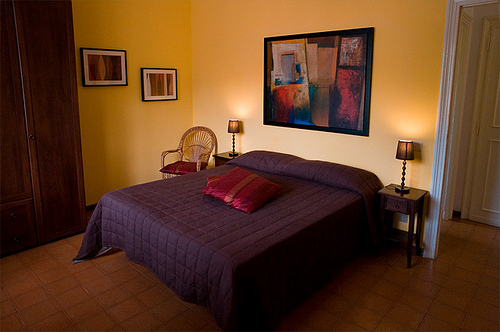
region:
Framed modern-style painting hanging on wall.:
[261, 25, 374, 137]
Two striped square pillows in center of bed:
[199, 163, 287, 215]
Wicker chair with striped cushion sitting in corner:
[158, 123, 218, 179]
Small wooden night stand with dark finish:
[374, 182, 428, 269]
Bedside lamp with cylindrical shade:
[391, 138, 414, 195]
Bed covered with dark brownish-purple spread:
[72, 149, 390, 330]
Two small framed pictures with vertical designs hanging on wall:
[77, 45, 179, 102]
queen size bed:
[128, 137, 397, 301]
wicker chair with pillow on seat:
[146, 114, 214, 178]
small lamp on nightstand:
[392, 130, 421, 197]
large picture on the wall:
[254, 23, 382, 135]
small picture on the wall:
[133, 61, 186, 105]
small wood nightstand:
[376, 179, 423, 264]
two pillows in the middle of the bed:
[200, 153, 274, 222]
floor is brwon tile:
[27, 220, 487, 319]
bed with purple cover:
[126, 137, 364, 309]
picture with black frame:
[81, 46, 133, 90]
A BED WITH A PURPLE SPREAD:
[68, 144, 385, 329]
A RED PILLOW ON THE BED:
[197, 164, 290, 216]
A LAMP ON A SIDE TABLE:
[374, 136, 433, 272]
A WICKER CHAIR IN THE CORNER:
[158, 120, 219, 177]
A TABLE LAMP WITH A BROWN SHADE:
[225, 115, 246, 159]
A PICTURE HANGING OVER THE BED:
[258, 21, 380, 139]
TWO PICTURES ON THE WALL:
[78, 43, 180, 105]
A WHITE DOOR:
[457, 9, 498, 234]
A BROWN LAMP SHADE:
[394, 136, 419, 162]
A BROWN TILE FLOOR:
[6, 255, 174, 330]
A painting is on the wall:
[261, 24, 377, 139]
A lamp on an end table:
[376, 135, 430, 271]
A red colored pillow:
[201, 163, 286, 215]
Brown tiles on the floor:
[1, 213, 498, 328]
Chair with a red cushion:
[158, 121, 219, 180]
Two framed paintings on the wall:
[78, 43, 180, 105]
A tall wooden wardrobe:
[1, 0, 89, 257]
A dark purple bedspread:
[71, 147, 403, 330]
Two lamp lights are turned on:
[223, 113, 421, 197]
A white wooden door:
[461, 17, 498, 228]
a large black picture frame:
[256, 24, 379, 136]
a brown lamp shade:
[394, 138, 416, 160]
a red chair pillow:
[163, 158, 201, 178]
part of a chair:
[158, 125, 213, 178]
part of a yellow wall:
[81, 9, 189, 50]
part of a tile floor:
[3, 228, 172, 330]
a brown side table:
[380, 178, 435, 267]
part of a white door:
[463, 21, 499, 222]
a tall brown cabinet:
[0, 0, 92, 249]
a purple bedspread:
[66, 148, 391, 320]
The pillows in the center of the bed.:
[204, 165, 282, 212]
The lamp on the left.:
[225, 115, 238, 155]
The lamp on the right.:
[397, 137, 413, 194]